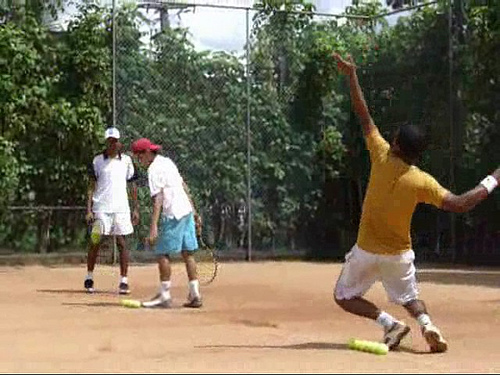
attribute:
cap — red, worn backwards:
[131, 136, 161, 155]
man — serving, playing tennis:
[328, 48, 499, 353]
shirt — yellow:
[356, 127, 447, 252]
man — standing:
[132, 136, 206, 310]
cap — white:
[103, 126, 122, 142]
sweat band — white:
[481, 173, 498, 192]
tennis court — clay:
[2, 259, 499, 374]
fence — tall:
[0, 1, 499, 260]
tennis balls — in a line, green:
[346, 335, 390, 357]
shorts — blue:
[153, 212, 199, 257]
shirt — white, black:
[83, 150, 139, 215]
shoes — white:
[380, 320, 450, 353]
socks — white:
[373, 307, 433, 327]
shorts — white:
[334, 243, 420, 305]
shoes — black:
[83, 279, 130, 295]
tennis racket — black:
[196, 222, 219, 287]